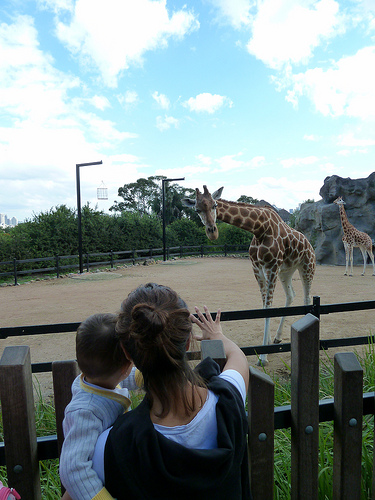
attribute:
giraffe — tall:
[173, 176, 325, 339]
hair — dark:
[114, 278, 194, 416]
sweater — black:
[111, 383, 236, 496]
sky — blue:
[1, 3, 371, 178]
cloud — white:
[170, 82, 246, 116]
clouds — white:
[61, 10, 251, 97]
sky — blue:
[49, 25, 374, 179]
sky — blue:
[2, 2, 373, 227]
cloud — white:
[52, 0, 199, 90]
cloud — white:
[240, 0, 345, 72]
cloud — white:
[266, 45, 371, 121]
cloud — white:
[182, 89, 232, 115]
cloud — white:
[79, 110, 136, 147]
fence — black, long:
[9, 247, 167, 270]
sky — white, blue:
[0, 0, 372, 156]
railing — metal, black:
[244, 297, 374, 374]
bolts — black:
[347, 415, 358, 427]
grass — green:
[316, 349, 362, 442]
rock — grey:
[29, 278, 33, 284]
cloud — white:
[56, 0, 206, 84]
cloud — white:
[245, 0, 353, 71]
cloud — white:
[284, 43, 372, 119]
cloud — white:
[108, 108, 109, 109]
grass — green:
[274, 427, 288, 498]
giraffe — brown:
[190, 181, 329, 310]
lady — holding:
[96, 278, 251, 498]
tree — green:
[132, 180, 179, 229]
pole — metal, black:
[71, 158, 106, 272]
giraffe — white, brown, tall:
[195, 150, 332, 332]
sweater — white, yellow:
[58, 376, 131, 498]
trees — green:
[0, 207, 246, 271]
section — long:
[2, 220, 41, 276]